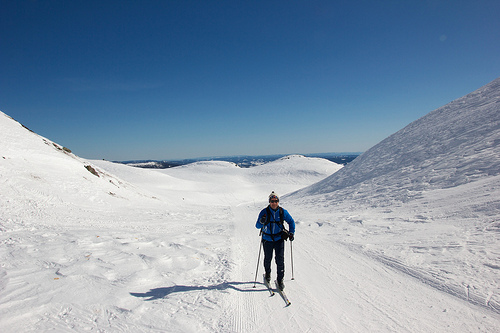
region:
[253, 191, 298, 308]
a man cross country skiing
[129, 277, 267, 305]
shadow of man in snow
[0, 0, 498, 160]
clear bright blue sky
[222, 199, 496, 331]
snowy pathway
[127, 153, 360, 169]
view of mountain-es terrain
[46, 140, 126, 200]
rocks on side of snowy hill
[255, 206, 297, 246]
blue jacket of skier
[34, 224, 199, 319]
small drifts in the snow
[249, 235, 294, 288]
two ski poles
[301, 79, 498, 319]
non smooth snowy hill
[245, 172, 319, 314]
man skiing on a trail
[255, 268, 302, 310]
Skis on the man's feet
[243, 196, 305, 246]
Blue jacket on the man.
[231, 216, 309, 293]
Ski poles in the man's hands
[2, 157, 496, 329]
The ground is white.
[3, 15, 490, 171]
Sky is clear and blue.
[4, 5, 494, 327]
Photo taken during the winter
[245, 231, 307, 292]
Black pants on the man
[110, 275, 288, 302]
Man's shadow cast to the left.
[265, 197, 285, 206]
Sunglasses on the man's face.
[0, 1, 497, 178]
the sky is blue.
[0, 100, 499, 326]
snow covering the ground.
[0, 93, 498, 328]
the snow is white.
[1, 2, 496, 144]
the sky is clear.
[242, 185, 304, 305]
the person is skiing.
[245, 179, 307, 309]
one person on the hill.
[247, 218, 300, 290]
man is holding ski poles.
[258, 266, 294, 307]
skis on man's feet.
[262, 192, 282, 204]
sunglasses on the man's face.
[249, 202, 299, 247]
man's coat is blue.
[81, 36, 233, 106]
Sky is blue color.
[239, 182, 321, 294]
One man is skiing.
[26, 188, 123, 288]
Ground is white color.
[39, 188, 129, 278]
Snow in ground.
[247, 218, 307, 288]
Man is holding ski poles in hand.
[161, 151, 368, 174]
Water is seen behind the snow.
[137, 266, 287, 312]
Shadow fallls on snow.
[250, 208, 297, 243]
Man is in blue jacket.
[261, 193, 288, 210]
Man is wearing black eye glass.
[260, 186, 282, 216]
Man is wearing cap.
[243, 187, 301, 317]
man skiing on ski slope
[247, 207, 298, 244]
blue outerwear jacket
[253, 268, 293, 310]
two skis on white snow slope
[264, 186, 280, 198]
white hat on person's head on ski slope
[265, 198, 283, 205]
black sunglasses on person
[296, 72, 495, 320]
steep snow covered slope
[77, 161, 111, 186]
tan rock surrounded by snow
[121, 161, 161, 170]
snow covered patch in horizon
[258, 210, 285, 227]
back sack straps across chest